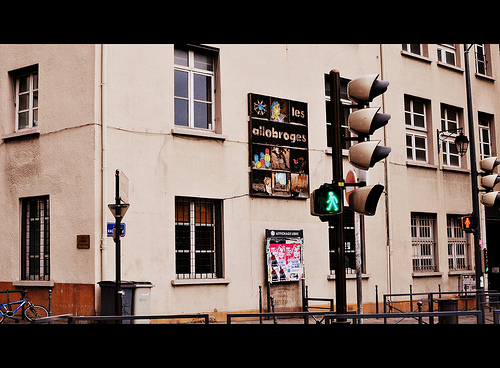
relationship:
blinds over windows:
[174, 197, 216, 223] [175, 192, 226, 284]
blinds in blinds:
[174, 199, 215, 225] [174, 197, 216, 223]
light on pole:
[344, 75, 386, 104] [328, 69, 348, 322]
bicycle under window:
[0, 285, 52, 324] [165, 51, 237, 130]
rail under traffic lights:
[66, 290, 499, 327] [308, 69, 390, 216]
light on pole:
[449, 123, 470, 156] [462, 44, 487, 343]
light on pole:
[465, 218, 471, 229] [453, 43, 483, 341]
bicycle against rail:
[2, 285, 52, 322] [3, 287, 30, 294]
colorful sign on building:
[248, 92, 311, 198] [136, 51, 435, 286]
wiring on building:
[105, 124, 170, 139] [3, 45, 497, 307]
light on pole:
[344, 75, 386, 104] [332, 76, 349, 358]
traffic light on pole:
[322, 66, 346, 219] [332, 76, 349, 358]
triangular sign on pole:
[107, 202, 128, 220] [115, 171, 119, 324]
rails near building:
[66, 288, 499, 325] [3, 45, 497, 307]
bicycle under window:
[0, 285, 52, 324] [4, 42, 481, 284]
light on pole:
[307, 182, 344, 219] [328, 69, 348, 322]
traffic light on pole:
[347, 105, 390, 135] [328, 69, 348, 322]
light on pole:
[349, 139, 392, 170] [328, 69, 348, 322]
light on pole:
[349, 184, 385, 216] [328, 69, 348, 322]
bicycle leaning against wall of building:
[0, 285, 52, 324] [3, 45, 497, 307]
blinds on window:
[174, 197, 216, 223] [171, 192, 225, 280]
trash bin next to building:
[105, 282, 131, 327] [3, 45, 497, 307]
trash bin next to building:
[132, 276, 154, 324] [3, 45, 497, 307]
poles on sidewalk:
[250, 282, 488, 324] [203, 309, 486, 331]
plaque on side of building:
[74, 232, 90, 249] [3, 45, 497, 307]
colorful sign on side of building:
[245, 91, 308, 200] [3, 45, 497, 307]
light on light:
[344, 75, 386, 104] [344, 75, 386, 104]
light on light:
[350, 107, 389, 137] [344, 75, 386, 104]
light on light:
[349, 139, 392, 170] [344, 75, 386, 104]